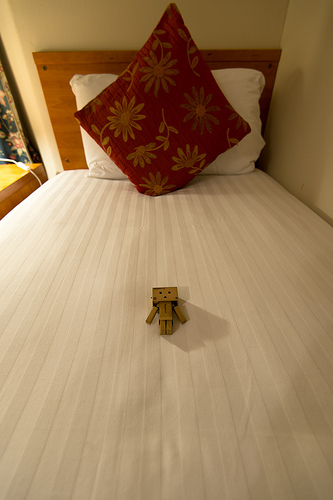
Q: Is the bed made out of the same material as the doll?
A: Yes, both the bed and the doll are made of wood.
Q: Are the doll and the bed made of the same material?
A: Yes, both the doll and the bed are made of wood.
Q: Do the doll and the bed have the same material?
A: Yes, both the doll and the bed are made of wood.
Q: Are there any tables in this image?
A: Yes, there is a table.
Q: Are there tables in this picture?
A: Yes, there is a table.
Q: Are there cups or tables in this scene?
A: Yes, there is a table.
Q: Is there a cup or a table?
A: Yes, there is a table.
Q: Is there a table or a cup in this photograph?
A: Yes, there is a table.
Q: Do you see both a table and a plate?
A: No, there is a table but no plates.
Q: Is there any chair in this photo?
A: No, there are no chairs.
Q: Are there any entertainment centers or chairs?
A: No, there are no chairs or entertainment centers.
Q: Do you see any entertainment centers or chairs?
A: No, there are no chairs or entertainment centers.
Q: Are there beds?
A: Yes, there is a bed.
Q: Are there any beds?
A: Yes, there is a bed.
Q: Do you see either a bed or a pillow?
A: Yes, there is a bed.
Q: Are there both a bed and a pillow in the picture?
A: Yes, there are both a bed and a pillow.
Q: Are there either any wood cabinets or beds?
A: Yes, there is a wood bed.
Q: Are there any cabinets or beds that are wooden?
A: Yes, the bed is wooden.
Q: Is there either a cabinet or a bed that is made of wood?
A: Yes, the bed is made of wood.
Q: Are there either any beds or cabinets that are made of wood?
A: Yes, the bed is made of wood.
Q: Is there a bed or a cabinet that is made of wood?
A: Yes, the bed is made of wood.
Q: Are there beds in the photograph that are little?
A: Yes, there is a little bed.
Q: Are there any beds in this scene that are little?
A: Yes, there is a bed that is little.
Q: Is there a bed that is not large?
A: Yes, there is a little bed.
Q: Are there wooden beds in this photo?
A: Yes, there is a wood bed.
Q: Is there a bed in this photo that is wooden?
A: Yes, there is a bed that is wooden.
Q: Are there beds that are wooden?
A: Yes, there is a bed that is wooden.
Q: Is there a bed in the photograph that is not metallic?
A: Yes, there is a wooden bed.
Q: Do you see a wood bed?
A: Yes, there is a bed that is made of wood.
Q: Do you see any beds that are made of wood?
A: Yes, there is a bed that is made of wood.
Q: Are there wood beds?
A: Yes, there is a bed that is made of wood.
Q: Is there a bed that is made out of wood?
A: Yes, there is a bed that is made of wood.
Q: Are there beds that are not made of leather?
A: Yes, there is a bed that is made of wood.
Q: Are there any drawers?
A: No, there are no drawers.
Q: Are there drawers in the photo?
A: No, there are no drawers.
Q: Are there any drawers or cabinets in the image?
A: No, there are no drawers or cabinets.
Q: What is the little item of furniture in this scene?
A: The piece of furniture is a bed.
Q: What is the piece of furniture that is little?
A: The piece of furniture is a bed.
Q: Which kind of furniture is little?
A: The furniture is a bed.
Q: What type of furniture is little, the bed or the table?
A: The bed is little.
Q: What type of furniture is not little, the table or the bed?
A: The table is not little.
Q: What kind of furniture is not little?
A: The furniture is a table.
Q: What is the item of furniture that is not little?
A: The piece of furniture is a table.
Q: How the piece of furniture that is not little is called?
A: The piece of furniture is a table.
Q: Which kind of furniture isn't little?
A: The furniture is a table.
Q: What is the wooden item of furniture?
A: The piece of furniture is a bed.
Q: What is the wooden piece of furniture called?
A: The piece of furniture is a bed.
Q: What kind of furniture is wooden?
A: The furniture is a bed.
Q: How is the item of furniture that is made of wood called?
A: The piece of furniture is a bed.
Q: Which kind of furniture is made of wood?
A: The furniture is a bed.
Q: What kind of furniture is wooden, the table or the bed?
A: The bed is wooden.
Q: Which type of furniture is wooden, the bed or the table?
A: The bed is wooden.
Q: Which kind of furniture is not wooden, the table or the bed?
A: The table is not wooden.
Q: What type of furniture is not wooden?
A: The furniture is a table.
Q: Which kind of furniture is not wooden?
A: The furniture is a table.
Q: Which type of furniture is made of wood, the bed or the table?
A: The bed is made of wood.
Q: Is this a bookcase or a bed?
A: This is a bed.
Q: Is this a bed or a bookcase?
A: This is a bed.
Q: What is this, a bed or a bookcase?
A: This is a bed.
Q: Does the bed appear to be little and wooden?
A: Yes, the bed is little and wooden.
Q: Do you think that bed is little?
A: Yes, the bed is little.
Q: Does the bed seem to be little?
A: Yes, the bed is little.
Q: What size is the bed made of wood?
A: The bed is little.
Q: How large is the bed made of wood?
A: The bed is little.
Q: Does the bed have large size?
A: No, the bed is little.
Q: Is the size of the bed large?
A: No, the bed is little.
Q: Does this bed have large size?
A: No, the bed is little.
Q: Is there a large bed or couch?
A: No, there is a bed but it is little.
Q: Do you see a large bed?
A: No, there is a bed but it is little.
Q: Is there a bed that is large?
A: No, there is a bed but it is little.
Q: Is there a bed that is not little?
A: No, there is a bed but it is little.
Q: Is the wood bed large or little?
A: The bed is little.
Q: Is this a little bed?
A: Yes, this is a little bed.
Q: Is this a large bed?
A: No, this is a little bed.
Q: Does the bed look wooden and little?
A: Yes, the bed is wooden and little.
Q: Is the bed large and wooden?
A: No, the bed is wooden but little.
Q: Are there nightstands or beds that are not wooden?
A: No, there is a bed but it is wooden.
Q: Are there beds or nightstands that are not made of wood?
A: No, there is a bed but it is made of wood.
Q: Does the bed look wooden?
A: Yes, the bed is wooden.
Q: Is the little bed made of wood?
A: Yes, the bed is made of wood.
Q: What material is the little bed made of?
A: The bed is made of wood.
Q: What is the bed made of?
A: The bed is made of wood.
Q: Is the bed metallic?
A: No, the bed is wooden.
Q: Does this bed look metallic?
A: No, the bed is wooden.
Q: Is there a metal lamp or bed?
A: No, there is a bed but it is wooden.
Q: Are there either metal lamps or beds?
A: No, there is a bed but it is wooden.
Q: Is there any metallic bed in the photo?
A: No, there is a bed but it is wooden.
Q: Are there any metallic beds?
A: No, there is a bed but it is wooden.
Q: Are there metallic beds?
A: No, there is a bed but it is wooden.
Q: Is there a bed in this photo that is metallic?
A: No, there is a bed but it is wooden.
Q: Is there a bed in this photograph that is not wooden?
A: No, there is a bed but it is wooden.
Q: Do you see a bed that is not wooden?
A: No, there is a bed but it is wooden.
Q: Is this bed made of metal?
A: No, the bed is made of wood.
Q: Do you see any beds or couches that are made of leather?
A: No, there is a bed but it is made of wood.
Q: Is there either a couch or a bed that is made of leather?
A: No, there is a bed but it is made of wood.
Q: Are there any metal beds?
A: No, there is a bed but it is made of wood.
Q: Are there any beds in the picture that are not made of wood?
A: No, there is a bed but it is made of wood.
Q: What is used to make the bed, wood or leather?
A: The bed is made of wood.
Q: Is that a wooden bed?
A: Yes, that is a wooden bed.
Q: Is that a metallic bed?
A: No, that is a wooden bed.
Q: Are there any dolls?
A: Yes, there is a doll.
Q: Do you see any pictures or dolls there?
A: Yes, there is a doll.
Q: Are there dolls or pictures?
A: Yes, there is a doll.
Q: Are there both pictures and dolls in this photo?
A: No, there is a doll but no pictures.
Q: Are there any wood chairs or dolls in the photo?
A: Yes, there is a wood doll.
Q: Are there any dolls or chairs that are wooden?
A: Yes, the doll is wooden.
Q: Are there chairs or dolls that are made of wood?
A: Yes, the doll is made of wood.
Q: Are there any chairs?
A: No, there are no chairs.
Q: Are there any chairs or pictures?
A: No, there are no chairs or pictures.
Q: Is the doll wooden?
A: Yes, the doll is wooden.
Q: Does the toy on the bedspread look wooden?
A: Yes, the doll is wooden.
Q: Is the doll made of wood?
A: Yes, the doll is made of wood.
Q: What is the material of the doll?
A: The doll is made of wood.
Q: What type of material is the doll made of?
A: The doll is made of wood.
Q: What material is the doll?
A: The doll is made of wood.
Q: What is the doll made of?
A: The doll is made of wood.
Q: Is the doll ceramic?
A: No, the doll is wooden.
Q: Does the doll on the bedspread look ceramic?
A: No, the doll is wooden.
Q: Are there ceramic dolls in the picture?
A: No, there is a doll but it is wooden.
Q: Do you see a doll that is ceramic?
A: No, there is a doll but it is wooden.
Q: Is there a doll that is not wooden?
A: No, there is a doll but it is wooden.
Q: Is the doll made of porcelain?
A: No, the doll is made of wood.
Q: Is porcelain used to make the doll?
A: No, the doll is made of wood.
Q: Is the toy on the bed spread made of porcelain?
A: No, the doll is made of wood.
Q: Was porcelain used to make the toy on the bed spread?
A: No, the doll is made of wood.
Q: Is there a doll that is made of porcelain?
A: No, there is a doll but it is made of wood.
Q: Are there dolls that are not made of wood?
A: No, there is a doll but it is made of wood.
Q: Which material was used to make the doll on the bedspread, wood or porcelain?
A: The doll is made of wood.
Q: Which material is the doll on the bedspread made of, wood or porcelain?
A: The doll is made of wood.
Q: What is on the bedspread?
A: The doll is on the bedspread.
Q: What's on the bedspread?
A: The doll is on the bedspread.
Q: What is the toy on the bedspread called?
A: The toy is a doll.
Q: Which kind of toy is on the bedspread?
A: The toy is a doll.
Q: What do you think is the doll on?
A: The doll is on the bedspread.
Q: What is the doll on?
A: The doll is on the bedspread.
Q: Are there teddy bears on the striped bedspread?
A: No, there is a doll on the bedspread.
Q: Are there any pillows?
A: Yes, there is a pillow.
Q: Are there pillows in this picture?
A: Yes, there is a pillow.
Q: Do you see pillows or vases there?
A: Yes, there is a pillow.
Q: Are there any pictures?
A: No, there are no pictures.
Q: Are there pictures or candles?
A: No, there are no pictures or candles.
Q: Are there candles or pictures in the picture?
A: No, there are no pictures or candles.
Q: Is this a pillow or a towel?
A: This is a pillow.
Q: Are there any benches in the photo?
A: No, there are no benches.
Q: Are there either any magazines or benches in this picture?
A: No, there are no benches or magazines.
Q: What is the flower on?
A: The flower is on the pillow.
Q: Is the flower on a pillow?
A: Yes, the flower is on a pillow.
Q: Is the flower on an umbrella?
A: No, the flower is on a pillow.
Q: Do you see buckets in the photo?
A: No, there are no buckets.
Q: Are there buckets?
A: No, there are no buckets.